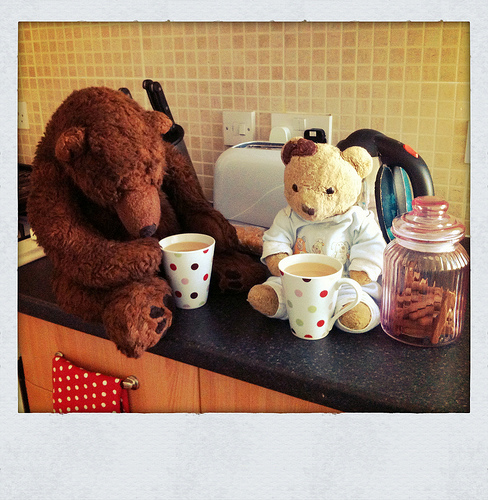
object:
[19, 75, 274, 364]
bear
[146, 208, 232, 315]
cup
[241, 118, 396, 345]
bear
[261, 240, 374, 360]
cup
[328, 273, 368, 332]
handle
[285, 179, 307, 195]
eye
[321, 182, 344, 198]
eye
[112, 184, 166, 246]
nose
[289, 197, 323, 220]
nose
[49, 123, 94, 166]
ear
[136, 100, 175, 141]
ear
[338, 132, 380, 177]
ear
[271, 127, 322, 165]
ear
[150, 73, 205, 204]
knives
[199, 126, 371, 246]
toaster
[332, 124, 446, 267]
iron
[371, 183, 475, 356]
jar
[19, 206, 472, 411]
counter